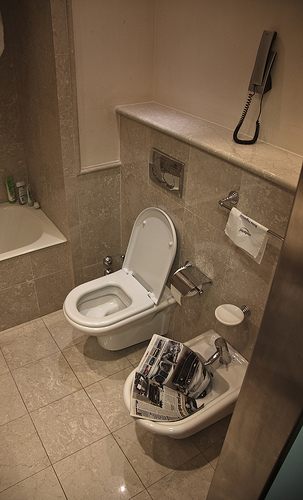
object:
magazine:
[128, 331, 212, 424]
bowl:
[121, 326, 252, 442]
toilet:
[61, 203, 179, 353]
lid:
[121, 205, 179, 307]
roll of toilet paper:
[168, 260, 214, 307]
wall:
[118, 111, 302, 364]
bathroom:
[0, 0, 303, 499]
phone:
[230, 25, 280, 149]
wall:
[70, 0, 301, 168]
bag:
[222, 206, 270, 264]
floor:
[1, 307, 229, 499]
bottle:
[5, 175, 17, 205]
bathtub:
[0, 194, 70, 329]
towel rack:
[216, 188, 286, 244]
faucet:
[203, 336, 231, 369]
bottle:
[26, 182, 34, 207]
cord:
[231, 85, 265, 148]